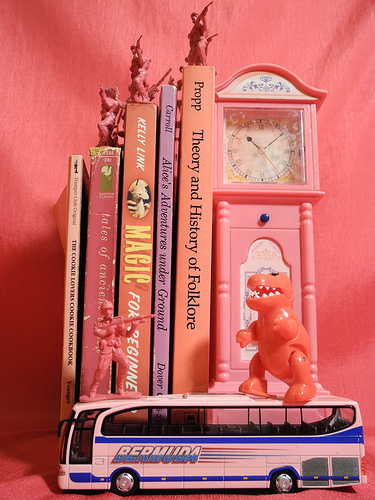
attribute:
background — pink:
[1, 2, 375, 500]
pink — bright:
[1, 1, 373, 498]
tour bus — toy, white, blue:
[46, 385, 374, 500]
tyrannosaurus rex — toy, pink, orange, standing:
[234, 266, 329, 408]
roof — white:
[68, 393, 359, 414]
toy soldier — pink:
[174, 0, 225, 67]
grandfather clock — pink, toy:
[204, 55, 334, 397]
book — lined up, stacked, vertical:
[167, 58, 219, 398]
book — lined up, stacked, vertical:
[147, 80, 185, 426]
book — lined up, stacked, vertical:
[111, 96, 159, 426]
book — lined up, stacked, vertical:
[73, 142, 125, 402]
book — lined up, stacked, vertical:
[52, 149, 87, 436]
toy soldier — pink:
[121, 32, 154, 107]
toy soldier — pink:
[90, 77, 126, 150]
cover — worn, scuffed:
[73, 141, 123, 456]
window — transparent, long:
[98, 404, 150, 439]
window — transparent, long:
[147, 407, 171, 440]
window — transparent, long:
[169, 406, 207, 438]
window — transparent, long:
[204, 407, 262, 440]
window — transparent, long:
[259, 406, 287, 439]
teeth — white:
[243, 281, 284, 306]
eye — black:
[264, 269, 284, 281]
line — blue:
[92, 434, 368, 446]